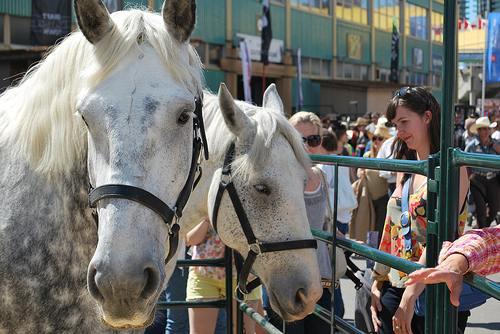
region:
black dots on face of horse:
[250, 198, 293, 234]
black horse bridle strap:
[260, 229, 321, 259]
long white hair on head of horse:
[30, 52, 82, 149]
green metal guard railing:
[331, 150, 421, 177]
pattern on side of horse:
[15, 210, 83, 318]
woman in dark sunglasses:
[288, 112, 333, 156]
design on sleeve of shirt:
[469, 238, 492, 268]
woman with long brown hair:
[370, 75, 455, 168]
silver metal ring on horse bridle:
[247, 240, 265, 260]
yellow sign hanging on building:
[340, 24, 382, 71]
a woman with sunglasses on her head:
[391, 81, 445, 157]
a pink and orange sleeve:
[440, 223, 498, 274]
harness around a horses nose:
[66, 115, 213, 303]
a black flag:
[387, 15, 404, 87]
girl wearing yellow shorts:
[178, 262, 265, 308]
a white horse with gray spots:
[204, 85, 340, 330]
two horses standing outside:
[5, 4, 334, 329]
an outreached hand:
[406, 230, 498, 307]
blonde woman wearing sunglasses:
[288, 110, 327, 165]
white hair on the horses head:
[243, 98, 320, 178]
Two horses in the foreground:
[3, 1, 329, 330]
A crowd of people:
[291, 71, 498, 331]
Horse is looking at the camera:
[50, 71, 209, 332]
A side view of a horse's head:
[204, 72, 346, 322]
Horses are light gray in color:
[5, 1, 325, 332]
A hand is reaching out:
[396, 212, 499, 317]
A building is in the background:
[0, 1, 496, 122]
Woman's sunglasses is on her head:
[384, 80, 439, 150]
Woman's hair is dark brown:
[370, 89, 453, 170]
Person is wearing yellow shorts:
[182, 261, 262, 321]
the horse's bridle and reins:
[211, 144, 259, 295]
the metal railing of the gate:
[317, 152, 459, 250]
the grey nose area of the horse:
[85, 258, 162, 317]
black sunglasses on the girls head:
[392, 84, 414, 99]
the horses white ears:
[218, 80, 254, 138]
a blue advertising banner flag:
[482, 10, 497, 81]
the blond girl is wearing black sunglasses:
[300, 131, 320, 146]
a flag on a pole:
[389, 18, 401, 84]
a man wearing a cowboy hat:
[470, 115, 497, 132]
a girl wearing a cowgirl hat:
[366, 125, 393, 148]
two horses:
[22, 40, 304, 332]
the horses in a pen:
[9, 15, 307, 326]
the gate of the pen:
[61, 105, 498, 310]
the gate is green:
[288, 130, 448, 328]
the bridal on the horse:
[79, 135, 213, 254]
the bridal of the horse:
[207, 158, 337, 291]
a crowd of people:
[317, 118, 432, 157]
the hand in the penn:
[382, 239, 498, 311]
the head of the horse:
[53, 8, 218, 315]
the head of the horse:
[212, 71, 351, 332]